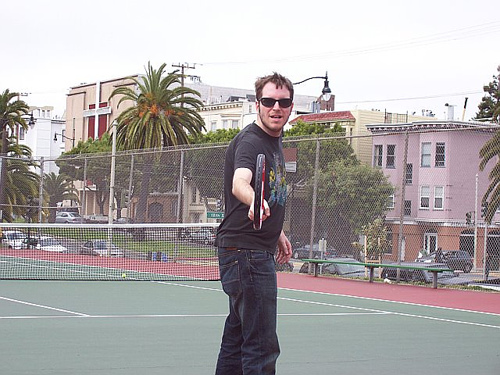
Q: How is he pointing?
A: Towards the camera.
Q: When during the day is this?
A: Afternoon.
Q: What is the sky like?
A: Overcast.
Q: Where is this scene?
A: Tennis court.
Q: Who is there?
A: A young man.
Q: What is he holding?
A: Tennis racket.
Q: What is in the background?
A: Buildings.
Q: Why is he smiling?
A: For the camera.